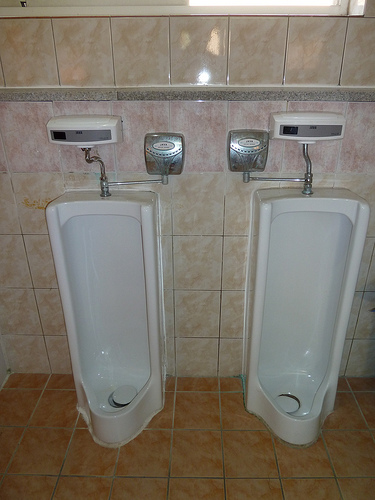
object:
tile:
[173, 393, 223, 433]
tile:
[170, 429, 224, 480]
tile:
[168, 478, 225, 499]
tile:
[7, 428, 73, 478]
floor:
[0, 376, 373, 498]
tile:
[321, 428, 373, 477]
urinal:
[243, 187, 371, 446]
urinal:
[45, 191, 167, 448]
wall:
[1, 16, 372, 378]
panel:
[144, 134, 185, 176]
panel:
[228, 129, 269, 173]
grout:
[1, 470, 374, 482]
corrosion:
[20, 197, 52, 210]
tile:
[173, 236, 224, 291]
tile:
[174, 290, 222, 338]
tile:
[175, 337, 220, 377]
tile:
[0, 288, 44, 337]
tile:
[0, 335, 52, 375]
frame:
[0, 0, 351, 18]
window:
[0, 0, 347, 15]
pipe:
[303, 143, 313, 195]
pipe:
[85, 147, 111, 196]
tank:
[45, 114, 124, 145]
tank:
[270, 111, 346, 144]